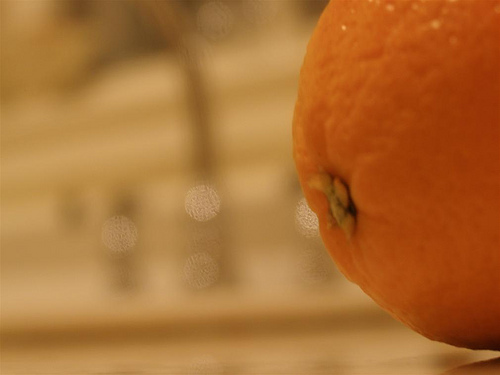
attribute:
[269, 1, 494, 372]
fruit — orange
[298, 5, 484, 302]
orange — textured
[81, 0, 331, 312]
sink — metal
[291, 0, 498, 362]
fruit — orange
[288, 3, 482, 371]
fruit — citrus, orange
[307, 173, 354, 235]
stalk — small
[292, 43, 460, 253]
orange — fresh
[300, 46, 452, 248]
orange — fresh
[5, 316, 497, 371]
counter — beige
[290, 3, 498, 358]
orange — fresh, big, ripe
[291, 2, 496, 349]
skin — orange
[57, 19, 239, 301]
faucet — chrome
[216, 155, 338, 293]
lever — chrome metal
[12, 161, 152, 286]
lever — chrome metal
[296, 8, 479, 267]
fruit — orange